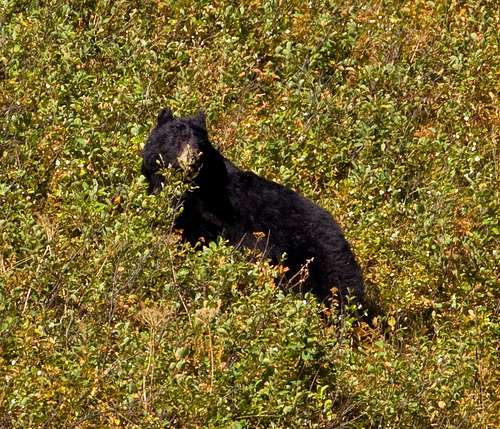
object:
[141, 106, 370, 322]
bear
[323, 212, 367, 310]
rear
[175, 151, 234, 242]
shadow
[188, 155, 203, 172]
snout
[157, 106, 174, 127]
ear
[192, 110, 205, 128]
ear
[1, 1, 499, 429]
leaves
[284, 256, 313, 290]
twig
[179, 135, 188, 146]
eye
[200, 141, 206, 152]
eye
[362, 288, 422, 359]
shadow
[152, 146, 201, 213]
branch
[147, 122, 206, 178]
face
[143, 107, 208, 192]
head